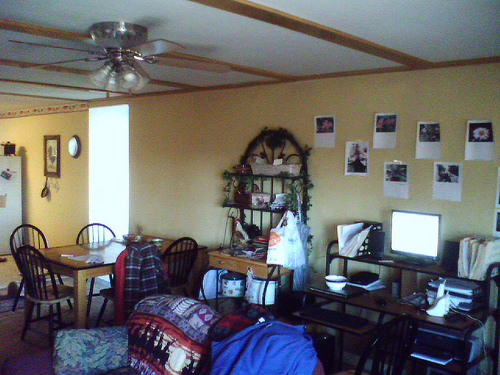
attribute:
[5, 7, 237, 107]
fan — ceiling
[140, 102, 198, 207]
wall — picture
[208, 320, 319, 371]
garment — blue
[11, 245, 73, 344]
chair — wood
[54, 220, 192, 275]
table — light wood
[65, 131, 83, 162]
clock — round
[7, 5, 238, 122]
ceiling fan — wood, metal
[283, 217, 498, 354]
desk — black, brown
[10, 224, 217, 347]
set — dining, wooden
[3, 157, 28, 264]
refrigerator — white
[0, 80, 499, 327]
yellowwall — yellow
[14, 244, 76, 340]
chair — brown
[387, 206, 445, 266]
monitor — flat screen, computer monitor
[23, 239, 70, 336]
chair — black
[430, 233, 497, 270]
folders — manilla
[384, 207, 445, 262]
monitor — on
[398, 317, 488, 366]
printer — black, grey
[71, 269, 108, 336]
leg — brown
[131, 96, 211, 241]
wall — smooth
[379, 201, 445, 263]
monitor — lit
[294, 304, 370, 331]
keyboard — black